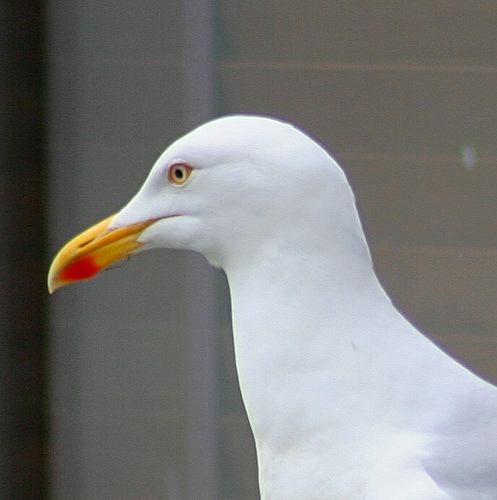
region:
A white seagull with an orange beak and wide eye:
[43, 119, 491, 498]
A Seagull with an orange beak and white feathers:
[44, 88, 423, 300]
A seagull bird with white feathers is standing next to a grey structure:
[34, 92, 423, 493]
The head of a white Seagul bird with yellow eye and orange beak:
[28, 84, 441, 380]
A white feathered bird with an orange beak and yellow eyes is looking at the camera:
[48, 84, 462, 458]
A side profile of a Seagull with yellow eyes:
[53, 127, 409, 433]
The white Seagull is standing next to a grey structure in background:
[43, 18, 493, 480]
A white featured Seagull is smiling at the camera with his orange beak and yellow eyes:
[18, 112, 458, 413]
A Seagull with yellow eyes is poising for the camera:
[23, 14, 492, 496]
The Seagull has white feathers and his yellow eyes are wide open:
[47, 112, 477, 467]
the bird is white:
[40, 102, 496, 498]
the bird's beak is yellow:
[25, 188, 179, 322]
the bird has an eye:
[145, 132, 216, 209]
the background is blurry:
[1, 0, 495, 497]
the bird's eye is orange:
[133, 147, 215, 213]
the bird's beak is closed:
[25, 191, 208, 328]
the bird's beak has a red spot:
[36, 198, 229, 322]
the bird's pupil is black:
[157, 150, 200, 191]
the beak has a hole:
[64, 225, 107, 257]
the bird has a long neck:
[175, 141, 432, 439]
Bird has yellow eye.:
[165, 172, 212, 205]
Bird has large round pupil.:
[158, 170, 196, 201]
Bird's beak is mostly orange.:
[41, 205, 188, 348]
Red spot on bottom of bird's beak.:
[46, 244, 154, 335]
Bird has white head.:
[88, 171, 390, 242]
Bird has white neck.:
[187, 237, 394, 353]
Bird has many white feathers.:
[177, 168, 424, 442]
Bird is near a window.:
[108, 97, 418, 449]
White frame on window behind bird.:
[105, 56, 251, 484]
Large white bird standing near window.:
[71, 187, 446, 487]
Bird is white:
[45, 112, 495, 498]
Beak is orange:
[46, 211, 151, 296]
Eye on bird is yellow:
[166, 159, 191, 185]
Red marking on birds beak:
[63, 257, 95, 283]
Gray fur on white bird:
[418, 378, 495, 498]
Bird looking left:
[46, 113, 494, 498]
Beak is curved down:
[44, 210, 144, 292]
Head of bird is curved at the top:
[110, 111, 362, 271]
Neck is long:
[225, 240, 410, 436]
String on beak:
[88, 252, 133, 274]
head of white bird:
[31, 100, 428, 340]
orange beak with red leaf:
[35, 201, 162, 311]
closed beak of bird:
[35, 198, 199, 305]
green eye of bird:
[149, 152, 210, 196]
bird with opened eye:
[151, 151, 207, 193]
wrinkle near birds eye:
[187, 151, 215, 180]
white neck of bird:
[241, 285, 385, 388]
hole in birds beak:
[68, 229, 108, 259]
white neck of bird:
[179, 252, 459, 393]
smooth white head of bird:
[203, 103, 362, 205]